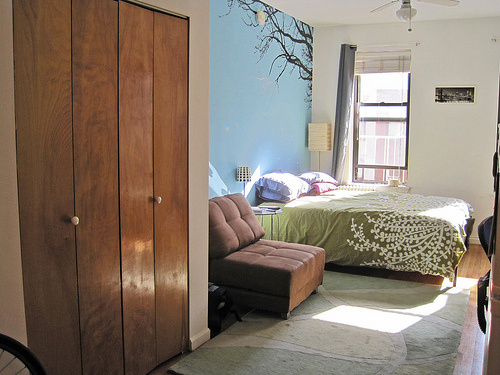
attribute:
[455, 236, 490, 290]
floor — hardwood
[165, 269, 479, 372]
rug — gray, white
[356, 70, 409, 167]
window — open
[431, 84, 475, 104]
picture — black, white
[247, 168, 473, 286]
bed — green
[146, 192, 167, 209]
knob — small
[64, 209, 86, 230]
knob — small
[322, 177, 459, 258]
designed cover — green, white, floral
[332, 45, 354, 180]
curtains — gray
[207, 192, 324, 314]
love seat — brown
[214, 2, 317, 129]
decal — black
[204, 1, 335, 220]
wall — blue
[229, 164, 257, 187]
lampshade — polka dot designed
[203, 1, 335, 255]
wall — blue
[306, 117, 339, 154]
shade — square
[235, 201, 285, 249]
table — circular